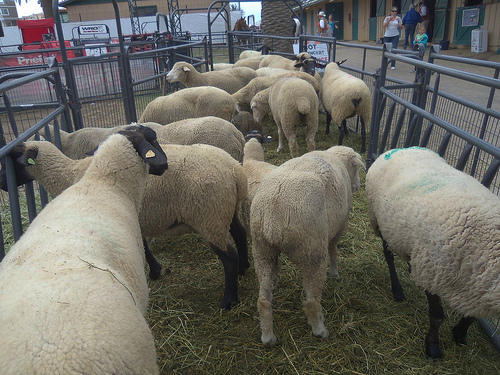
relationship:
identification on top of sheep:
[140, 149, 159, 162] [2, 123, 170, 374]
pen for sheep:
[0, 0, 498, 369] [159, 58, 253, 92]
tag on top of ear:
[140, 149, 159, 162] [135, 138, 161, 166]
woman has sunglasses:
[383, 6, 407, 70] [392, 8, 399, 15]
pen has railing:
[4, 0, 499, 369] [235, 27, 301, 43]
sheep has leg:
[250, 137, 378, 349] [294, 256, 333, 340]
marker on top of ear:
[140, 149, 159, 162] [135, 138, 161, 166]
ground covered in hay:
[89, 99, 459, 367] [159, 297, 478, 375]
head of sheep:
[98, 119, 176, 181] [296, 57, 321, 75]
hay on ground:
[159, 297, 478, 375] [151, 168, 450, 373]